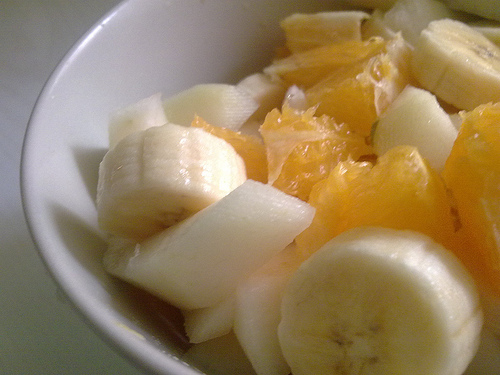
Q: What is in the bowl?
A: Fruit in the bowl.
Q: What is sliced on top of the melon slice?
A: A banana slice.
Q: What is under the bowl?
A: A white table.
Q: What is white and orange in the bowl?
A: It is fruit.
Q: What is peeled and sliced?
A: Fruit is peeled and sliced.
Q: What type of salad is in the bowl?
A: A fruit salad.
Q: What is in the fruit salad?
A: Banana is in the fruit salad.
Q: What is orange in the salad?
A: Oranges are orange in salad.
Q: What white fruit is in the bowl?
A: Banana.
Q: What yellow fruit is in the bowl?
A: Orange.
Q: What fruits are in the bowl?
A: Banana and orange.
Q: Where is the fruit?
A: In a bowl.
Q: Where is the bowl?
A: On a table.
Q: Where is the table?
A: Under the bowl.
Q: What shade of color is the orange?
A: Orange.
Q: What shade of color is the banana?
A: White.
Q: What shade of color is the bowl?
A: White.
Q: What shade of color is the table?
A: White.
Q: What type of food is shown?
A: Fruit.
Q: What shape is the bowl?
A: Round.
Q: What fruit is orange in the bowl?
A: Oranges.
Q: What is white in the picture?
A: The bowl.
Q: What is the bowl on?
A: A table.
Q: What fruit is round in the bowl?
A: Bananas.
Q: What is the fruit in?
A: A bowl.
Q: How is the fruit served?
A: Cut up in a bowl.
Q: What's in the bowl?
A: Fruit.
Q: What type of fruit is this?
A: Bananas and oranges.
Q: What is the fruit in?
A: A bowl.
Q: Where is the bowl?
A: On a table.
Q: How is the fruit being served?
A: It's sliced.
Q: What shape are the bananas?
A: Circles.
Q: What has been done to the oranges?
A: They have been peeled.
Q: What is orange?
A: The orange.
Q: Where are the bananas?
A: The bowl.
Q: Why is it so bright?
A: Lights are on.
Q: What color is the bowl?
A: White.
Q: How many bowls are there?
A: One.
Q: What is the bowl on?
A: The table.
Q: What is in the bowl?
A: Fruit.